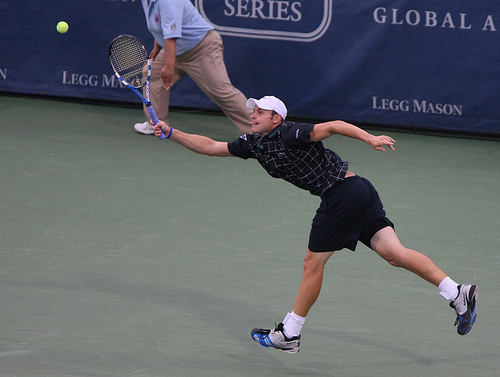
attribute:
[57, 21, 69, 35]
tennis ball — green, yellow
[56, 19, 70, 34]
ball — small, green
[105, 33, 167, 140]
racket — blue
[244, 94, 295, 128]
cap — white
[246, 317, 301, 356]
feet — apart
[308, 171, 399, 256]
shorts — black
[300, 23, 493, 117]
wall — blue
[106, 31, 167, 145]
tennis racket — white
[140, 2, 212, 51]
shirt — light blue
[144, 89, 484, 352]
tennis player — running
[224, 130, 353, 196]
shirt — black